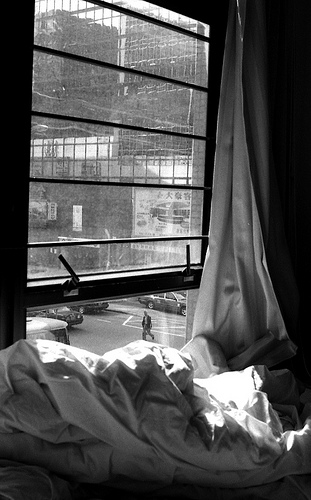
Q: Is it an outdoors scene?
A: Yes, it is outdoors.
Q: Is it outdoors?
A: Yes, it is outdoors.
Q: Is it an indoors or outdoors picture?
A: It is outdoors.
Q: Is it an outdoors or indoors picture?
A: It is outdoors.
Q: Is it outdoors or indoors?
A: It is outdoors.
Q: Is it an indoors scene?
A: No, it is outdoors.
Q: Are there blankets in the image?
A: Yes, there is a blanket.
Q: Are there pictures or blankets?
A: Yes, there is a blanket.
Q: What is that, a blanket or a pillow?
A: That is a blanket.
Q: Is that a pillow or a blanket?
A: That is a blanket.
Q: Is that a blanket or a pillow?
A: That is a blanket.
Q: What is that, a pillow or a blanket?
A: That is a blanket.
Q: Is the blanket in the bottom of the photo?
A: Yes, the blanket is in the bottom of the image.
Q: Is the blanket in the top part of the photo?
A: No, the blanket is in the bottom of the image.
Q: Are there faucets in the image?
A: No, there are no faucets.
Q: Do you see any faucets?
A: No, there are no faucets.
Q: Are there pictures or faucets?
A: No, there are no faucets or pictures.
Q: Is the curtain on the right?
A: Yes, the curtain is on the right of the image.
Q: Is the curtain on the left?
A: No, the curtain is on the right of the image.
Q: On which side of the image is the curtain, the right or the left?
A: The curtain is on the right of the image.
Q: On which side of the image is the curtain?
A: The curtain is on the right of the image.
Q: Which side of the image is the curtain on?
A: The curtain is on the right of the image.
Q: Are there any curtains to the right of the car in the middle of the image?
A: Yes, there is a curtain to the right of the car.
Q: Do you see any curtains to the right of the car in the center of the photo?
A: Yes, there is a curtain to the right of the car.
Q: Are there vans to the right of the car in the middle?
A: No, there is a curtain to the right of the car.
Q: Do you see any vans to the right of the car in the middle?
A: No, there is a curtain to the right of the car.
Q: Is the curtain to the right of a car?
A: Yes, the curtain is to the right of a car.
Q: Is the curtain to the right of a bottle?
A: No, the curtain is to the right of a car.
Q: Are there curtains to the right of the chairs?
A: Yes, there is a curtain to the right of the chairs.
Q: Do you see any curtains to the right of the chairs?
A: Yes, there is a curtain to the right of the chairs.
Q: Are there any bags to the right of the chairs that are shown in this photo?
A: No, there is a curtain to the right of the chairs.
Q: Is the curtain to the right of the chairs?
A: Yes, the curtain is to the right of the chairs.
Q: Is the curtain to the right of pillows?
A: No, the curtain is to the right of the chairs.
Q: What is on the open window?
A: The curtain is on the window.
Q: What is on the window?
A: The curtain is on the window.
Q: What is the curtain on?
A: The curtain is on the window.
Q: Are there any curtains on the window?
A: Yes, there is a curtain on the window.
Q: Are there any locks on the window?
A: No, there is a curtain on the window.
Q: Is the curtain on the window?
A: Yes, the curtain is on the window.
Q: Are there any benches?
A: No, there are no benches.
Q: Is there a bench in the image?
A: No, there are no benches.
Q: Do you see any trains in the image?
A: No, there are no trains.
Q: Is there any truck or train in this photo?
A: No, there are no trains or trucks.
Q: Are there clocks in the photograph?
A: No, there are no clocks.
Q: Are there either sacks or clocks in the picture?
A: No, there are no clocks or sacks.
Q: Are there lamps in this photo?
A: Yes, there is a lamp.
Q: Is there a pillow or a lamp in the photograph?
A: Yes, there is a lamp.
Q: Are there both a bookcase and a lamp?
A: No, there is a lamp but no bookcases.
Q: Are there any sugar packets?
A: No, there are no sugar packets.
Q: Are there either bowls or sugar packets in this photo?
A: No, there are no sugar packets or bowls.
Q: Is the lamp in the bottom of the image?
A: Yes, the lamp is in the bottom of the image.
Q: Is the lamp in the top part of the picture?
A: No, the lamp is in the bottom of the image.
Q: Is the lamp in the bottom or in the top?
A: The lamp is in the bottom of the image.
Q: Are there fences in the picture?
A: No, there are no fences.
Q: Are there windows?
A: Yes, there is a window.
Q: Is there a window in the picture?
A: Yes, there is a window.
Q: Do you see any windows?
A: Yes, there is a window.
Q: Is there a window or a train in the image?
A: Yes, there is a window.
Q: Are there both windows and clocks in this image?
A: No, there is a window but no clocks.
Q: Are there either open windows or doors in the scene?
A: Yes, there is an open window.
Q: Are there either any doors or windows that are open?
A: Yes, the window is open.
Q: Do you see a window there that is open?
A: Yes, there is an open window.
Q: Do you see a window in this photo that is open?
A: Yes, there is a window that is open.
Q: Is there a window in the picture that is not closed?
A: Yes, there is a open window.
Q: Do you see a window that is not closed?
A: Yes, there is a open window.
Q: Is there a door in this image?
A: No, there are no doors.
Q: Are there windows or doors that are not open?
A: No, there is a window but it is open.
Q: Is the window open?
A: Yes, the window is open.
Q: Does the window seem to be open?
A: Yes, the window is open.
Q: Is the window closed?
A: No, the window is open.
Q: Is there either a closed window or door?
A: No, there is a window but it is open.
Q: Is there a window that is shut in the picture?
A: No, there is a window but it is open.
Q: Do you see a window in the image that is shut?
A: No, there is a window but it is open.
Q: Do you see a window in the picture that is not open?
A: No, there is a window but it is open.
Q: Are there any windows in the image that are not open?
A: No, there is a window but it is open.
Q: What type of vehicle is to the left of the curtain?
A: The vehicle is a car.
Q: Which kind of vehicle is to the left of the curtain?
A: The vehicle is a car.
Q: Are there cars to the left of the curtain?
A: Yes, there is a car to the left of the curtain.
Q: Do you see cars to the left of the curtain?
A: Yes, there is a car to the left of the curtain.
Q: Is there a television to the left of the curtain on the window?
A: No, there is a car to the left of the curtain.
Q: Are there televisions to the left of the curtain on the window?
A: No, there is a car to the left of the curtain.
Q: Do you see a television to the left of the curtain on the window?
A: No, there is a car to the left of the curtain.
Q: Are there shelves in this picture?
A: No, there are no shelves.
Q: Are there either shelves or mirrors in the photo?
A: No, there are no shelves or mirrors.